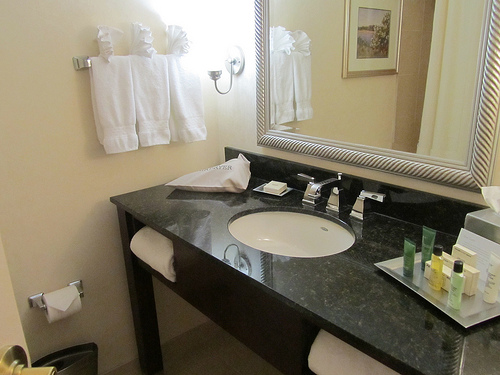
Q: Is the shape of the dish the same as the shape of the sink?
A: No, the sink is round and the dish is square.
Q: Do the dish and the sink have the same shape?
A: No, the sink is round and the dish is square.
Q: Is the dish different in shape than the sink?
A: Yes, the sink is round and the dish is square.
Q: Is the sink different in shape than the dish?
A: Yes, the sink is round and the dish is square.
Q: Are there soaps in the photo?
A: Yes, there is a soap.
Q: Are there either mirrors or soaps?
A: Yes, there is a soap.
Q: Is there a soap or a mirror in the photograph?
A: Yes, there is a soap.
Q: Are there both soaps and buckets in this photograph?
A: No, there is a soap but no buckets.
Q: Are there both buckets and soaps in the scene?
A: No, there is a soap but no buckets.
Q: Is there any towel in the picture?
A: Yes, there is a towel.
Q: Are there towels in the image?
A: Yes, there is a towel.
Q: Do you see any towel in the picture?
A: Yes, there is a towel.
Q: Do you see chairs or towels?
A: Yes, there is a towel.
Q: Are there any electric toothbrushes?
A: No, there are no electric toothbrushes.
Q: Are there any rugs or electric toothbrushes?
A: No, there are no electric toothbrushes or rugs.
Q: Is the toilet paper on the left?
A: Yes, the toilet paper is on the left of the image.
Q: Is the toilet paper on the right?
A: No, the toilet paper is on the left of the image.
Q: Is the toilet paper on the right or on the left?
A: The toilet paper is on the left of the image.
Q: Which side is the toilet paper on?
A: The toilet paper is on the left of the image.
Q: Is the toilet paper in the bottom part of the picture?
A: Yes, the toilet paper is in the bottom of the image.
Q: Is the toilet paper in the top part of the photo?
A: No, the toilet paper is in the bottom of the image.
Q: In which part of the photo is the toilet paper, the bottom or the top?
A: The toilet paper is in the bottom of the image.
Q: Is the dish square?
A: Yes, the dish is square.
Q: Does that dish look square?
A: Yes, the dish is square.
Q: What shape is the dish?
A: The dish is square.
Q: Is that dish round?
A: No, the dish is square.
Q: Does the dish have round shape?
A: No, the dish is square.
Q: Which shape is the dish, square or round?
A: The dish is square.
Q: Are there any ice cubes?
A: No, there are no ice cubes.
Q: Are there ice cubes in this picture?
A: No, there are no ice cubes.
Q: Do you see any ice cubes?
A: No, there are no ice cubes.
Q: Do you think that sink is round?
A: Yes, the sink is round.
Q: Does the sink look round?
A: Yes, the sink is round.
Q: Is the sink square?
A: No, the sink is round.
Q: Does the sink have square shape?
A: No, the sink is round.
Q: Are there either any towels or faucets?
A: Yes, there is a towel.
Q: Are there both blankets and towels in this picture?
A: No, there is a towel but no blankets.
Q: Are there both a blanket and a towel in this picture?
A: No, there is a towel but no blankets.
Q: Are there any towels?
A: Yes, there is a towel.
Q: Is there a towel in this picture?
A: Yes, there is a towel.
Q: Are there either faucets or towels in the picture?
A: Yes, there is a towel.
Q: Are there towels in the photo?
A: Yes, there is a towel.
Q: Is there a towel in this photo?
A: Yes, there is a towel.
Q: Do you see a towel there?
A: Yes, there is a towel.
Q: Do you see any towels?
A: Yes, there is a towel.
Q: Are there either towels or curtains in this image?
A: Yes, there is a towel.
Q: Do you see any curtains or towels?
A: Yes, there is a towel.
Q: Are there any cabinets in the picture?
A: No, there are no cabinets.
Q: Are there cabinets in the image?
A: No, there are no cabinets.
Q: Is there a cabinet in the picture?
A: No, there are no cabinets.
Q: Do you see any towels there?
A: Yes, there is a towel.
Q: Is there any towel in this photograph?
A: Yes, there is a towel.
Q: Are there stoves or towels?
A: Yes, there is a towel.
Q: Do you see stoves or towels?
A: Yes, there is a towel.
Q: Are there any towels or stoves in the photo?
A: Yes, there is a towel.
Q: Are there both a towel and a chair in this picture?
A: No, there is a towel but no chairs.